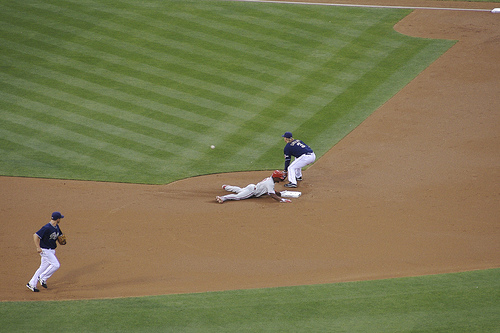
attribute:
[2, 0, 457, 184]
grass — neatly cut, green grass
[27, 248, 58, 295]
pants — white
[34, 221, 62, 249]
shirt — white, blue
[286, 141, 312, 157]
shirt — blue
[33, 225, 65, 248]
shirt — blue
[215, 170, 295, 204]
runner — safe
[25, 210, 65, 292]
player — running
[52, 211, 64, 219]
hat — blue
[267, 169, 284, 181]
helmet — red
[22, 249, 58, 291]
pants — white, stripe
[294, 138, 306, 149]
number — white